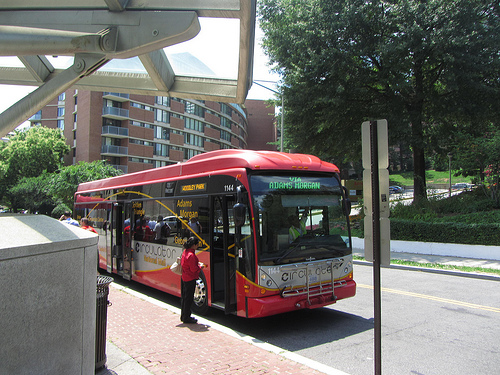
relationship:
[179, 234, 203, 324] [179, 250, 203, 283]
person wearing shirt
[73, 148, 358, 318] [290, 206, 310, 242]
bus has driver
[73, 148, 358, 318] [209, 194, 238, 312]
bus has door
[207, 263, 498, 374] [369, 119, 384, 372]
street has pole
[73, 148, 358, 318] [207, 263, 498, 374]
bus on street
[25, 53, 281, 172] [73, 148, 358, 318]
building behind bus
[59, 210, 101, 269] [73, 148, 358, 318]
people walking next to bus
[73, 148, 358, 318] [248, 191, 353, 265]
bus has windshield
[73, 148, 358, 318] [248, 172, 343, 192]
bus has display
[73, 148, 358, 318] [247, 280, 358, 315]
bus has bumper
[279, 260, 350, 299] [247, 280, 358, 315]
rack on bumper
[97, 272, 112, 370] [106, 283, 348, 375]
trash bin sitting on side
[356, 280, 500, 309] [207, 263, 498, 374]
line painted on street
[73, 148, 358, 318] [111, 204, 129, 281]
bus has rear door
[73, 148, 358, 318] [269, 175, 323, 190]
bus has word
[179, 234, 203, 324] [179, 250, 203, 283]
person has shirt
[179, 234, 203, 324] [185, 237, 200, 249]
person has hair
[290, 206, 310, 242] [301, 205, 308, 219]
driver has hand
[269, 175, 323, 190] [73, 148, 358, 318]
word on bus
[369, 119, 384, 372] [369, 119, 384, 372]
pole on pole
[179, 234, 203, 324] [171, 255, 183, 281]
person holding purse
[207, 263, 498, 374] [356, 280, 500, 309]
street has line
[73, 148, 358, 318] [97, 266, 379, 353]
bus has shadow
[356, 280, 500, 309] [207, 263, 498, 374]
line on street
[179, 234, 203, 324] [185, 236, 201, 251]
person has head